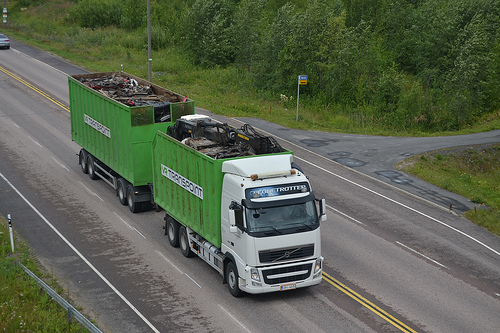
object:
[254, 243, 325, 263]
grill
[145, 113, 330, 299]
truck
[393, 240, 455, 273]
lines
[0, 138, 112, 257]
water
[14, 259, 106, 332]
railing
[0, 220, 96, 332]
weeds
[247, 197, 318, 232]
windshield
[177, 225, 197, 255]
wheel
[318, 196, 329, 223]
mirror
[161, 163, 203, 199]
word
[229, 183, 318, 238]
cab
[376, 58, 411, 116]
tree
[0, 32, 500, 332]
highway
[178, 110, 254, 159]
pile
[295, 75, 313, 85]
sign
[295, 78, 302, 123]
pole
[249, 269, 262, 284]
headlight